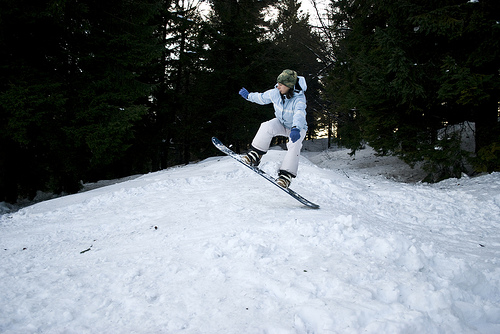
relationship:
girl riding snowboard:
[238, 68, 309, 189] [207, 135, 319, 209]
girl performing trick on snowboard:
[238, 68, 309, 189] [209, 135, 324, 215]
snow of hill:
[3, 174, 498, 331] [19, 150, 483, 303]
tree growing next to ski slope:
[2, 0, 182, 210] [29, 137, 329, 289]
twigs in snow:
[64, 220, 106, 274] [25, 196, 473, 332]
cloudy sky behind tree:
[300, 2, 332, 27] [312, 3, 498, 179]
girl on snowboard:
[238, 68, 309, 189] [207, 135, 319, 209]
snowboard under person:
[202, 134, 329, 216] [227, 55, 318, 190]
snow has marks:
[3, 174, 498, 331] [230, 211, 368, 314]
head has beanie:
[275, 67, 302, 98] [277, 70, 297, 85]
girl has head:
[238, 68, 309, 189] [275, 67, 302, 98]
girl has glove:
[238, 68, 309, 189] [238, 91, 278, 121]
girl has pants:
[238, 68, 309, 189] [252, 115, 307, 178]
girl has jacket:
[238, 68, 309, 189] [257, 84, 319, 134]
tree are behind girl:
[2, 0, 182, 210] [238, 68, 309, 189]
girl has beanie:
[240, 66, 310, 191] [277, 69, 297, 89]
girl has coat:
[238, 68, 309, 189] [242, 83, 318, 131]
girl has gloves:
[238, 68, 309, 189] [233, 83, 303, 140]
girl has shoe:
[240, 66, 310, 191] [273, 162, 295, 188]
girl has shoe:
[240, 66, 310, 191] [240, 145, 262, 170]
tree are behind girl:
[2, 0, 182, 210] [209, 66, 356, 198]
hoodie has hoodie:
[247, 75, 309, 133] [290, 71, 313, 98]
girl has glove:
[238, 68, 309, 189] [238, 86, 248, 99]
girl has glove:
[238, 68, 309, 189] [290, 125, 300, 141]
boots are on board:
[238, 145, 298, 194] [202, 119, 321, 219]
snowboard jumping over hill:
[202, 134, 329, 216] [0, 129, 499, 333]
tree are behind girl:
[312, 0, 499, 179] [199, 54, 373, 209]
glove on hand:
[233, 82, 250, 99] [282, 126, 302, 148]